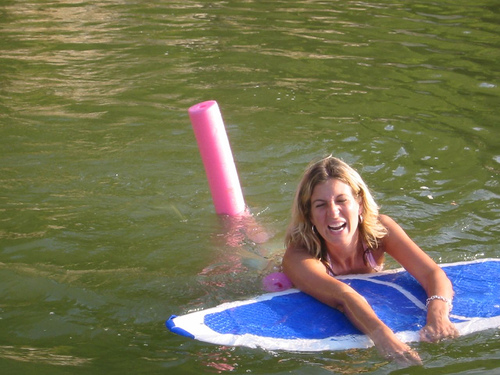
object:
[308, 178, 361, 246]
face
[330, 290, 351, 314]
elbow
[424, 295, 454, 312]
bracelet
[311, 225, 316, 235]
earring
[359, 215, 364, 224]
earring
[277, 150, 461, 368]
blond woman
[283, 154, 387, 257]
hair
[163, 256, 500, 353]
surfboard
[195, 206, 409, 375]
reflection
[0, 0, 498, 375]
green water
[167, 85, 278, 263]
foam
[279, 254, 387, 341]
arm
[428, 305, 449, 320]
wrist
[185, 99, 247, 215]
pool noodle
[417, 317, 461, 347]
hand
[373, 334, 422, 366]
hand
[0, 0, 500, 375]
water